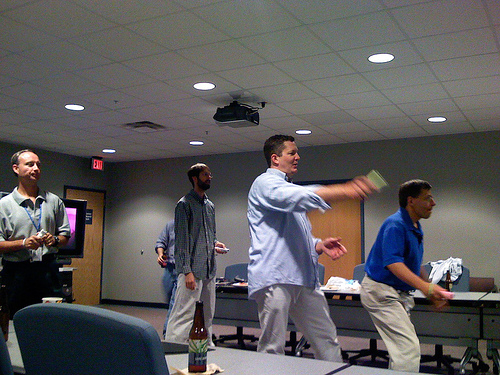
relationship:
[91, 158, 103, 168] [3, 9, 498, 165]
sign attached to ceiling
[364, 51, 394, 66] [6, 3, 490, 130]
light fixture on ceiling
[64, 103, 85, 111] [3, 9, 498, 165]
light on ceiling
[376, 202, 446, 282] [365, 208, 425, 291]
man wears shirt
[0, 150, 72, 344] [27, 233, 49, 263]
man wears card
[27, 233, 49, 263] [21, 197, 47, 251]
card on lanyard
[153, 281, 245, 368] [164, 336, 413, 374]
bottle on table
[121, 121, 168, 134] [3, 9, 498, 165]
air vent in ceiling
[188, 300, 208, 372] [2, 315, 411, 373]
bottle on table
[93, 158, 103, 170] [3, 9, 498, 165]
sign on ceiling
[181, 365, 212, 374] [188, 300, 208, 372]
napkin under bottle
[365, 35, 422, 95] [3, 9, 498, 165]
light in ceiling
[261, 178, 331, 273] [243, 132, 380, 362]
shirt on man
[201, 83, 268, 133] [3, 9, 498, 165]
protector in ceiling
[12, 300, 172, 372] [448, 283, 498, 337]
chair at a table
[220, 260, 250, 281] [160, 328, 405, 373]
chair at a table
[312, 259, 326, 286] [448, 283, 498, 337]
chair at a table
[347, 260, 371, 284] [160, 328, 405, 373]
chair at a table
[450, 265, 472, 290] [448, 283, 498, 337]
chair at a table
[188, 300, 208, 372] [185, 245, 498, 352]
bottle on table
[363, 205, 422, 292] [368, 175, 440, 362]
shirt on man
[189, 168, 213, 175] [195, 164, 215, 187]
glasses on face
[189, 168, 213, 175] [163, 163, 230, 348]
glasses on man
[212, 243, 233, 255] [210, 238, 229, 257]
wii control in man's hand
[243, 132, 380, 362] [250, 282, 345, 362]
man wearing pants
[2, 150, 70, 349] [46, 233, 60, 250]
man wearing watch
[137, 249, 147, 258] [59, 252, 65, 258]
protector for door knob